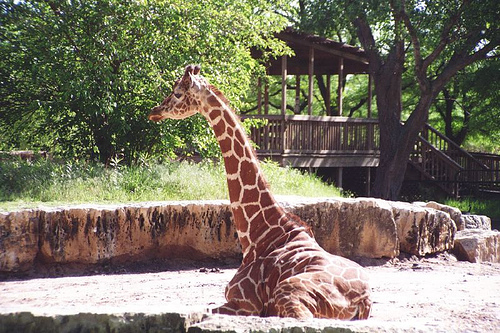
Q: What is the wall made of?
A: Stone.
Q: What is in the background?
A: Trees.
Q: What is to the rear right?
A: Tall tree.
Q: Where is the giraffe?
A: Enclosure.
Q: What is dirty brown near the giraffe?
A: Stone embankment.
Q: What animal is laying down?
A: Giraffe.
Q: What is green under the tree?
A: Bushes.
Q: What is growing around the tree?
A: Grass.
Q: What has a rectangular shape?
A: Stone blocks.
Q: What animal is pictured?
A: Giraffe.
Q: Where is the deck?
A: Behind the giraffe.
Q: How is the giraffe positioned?
A: Sitting.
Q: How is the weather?
A: Clear.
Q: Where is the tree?
A: Beside the deck.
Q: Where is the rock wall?
A: Between the deck and the giraffe.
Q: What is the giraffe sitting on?
A: Dirt.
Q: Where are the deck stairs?
A: To the right of the tree.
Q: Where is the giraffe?
A: Zoo.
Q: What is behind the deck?
A: Trees.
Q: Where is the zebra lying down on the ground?
A: National park.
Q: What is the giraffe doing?
A: Laying it the giraffe pen.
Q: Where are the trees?
A: Surrounding the giraffe habitat.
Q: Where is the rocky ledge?
A: Around the giraffe pen.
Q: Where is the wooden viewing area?
A: Behind the trees.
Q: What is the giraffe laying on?
A: Dead grass on the ground.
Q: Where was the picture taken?
A: Zoo.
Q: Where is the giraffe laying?
A: Ground.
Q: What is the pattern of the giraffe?
A: Spotted.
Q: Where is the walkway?
A: In the back.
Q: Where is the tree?
A: Behind the ledge.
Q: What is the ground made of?
A: Dirt.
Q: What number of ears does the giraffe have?
A: 2.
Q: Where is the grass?
A: Behind the ledge.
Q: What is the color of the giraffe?
A: Brown and white.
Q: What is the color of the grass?
A: Green.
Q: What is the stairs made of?
A: Wood.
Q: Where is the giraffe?
A: On the ground.